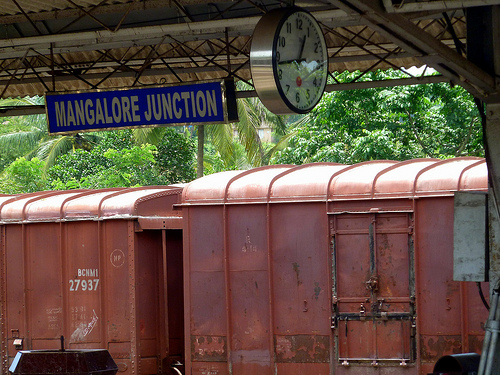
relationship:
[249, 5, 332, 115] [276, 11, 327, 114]
clock reads 12:43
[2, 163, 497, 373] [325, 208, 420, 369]
train car has door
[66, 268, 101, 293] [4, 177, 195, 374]
writing outside of train car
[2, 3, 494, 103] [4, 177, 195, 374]
awning over top of train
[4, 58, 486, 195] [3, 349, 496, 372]
greenery along train track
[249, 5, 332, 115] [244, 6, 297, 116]
clock made of metal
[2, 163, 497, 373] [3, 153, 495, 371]
train car part of set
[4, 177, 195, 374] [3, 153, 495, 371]
train car part of set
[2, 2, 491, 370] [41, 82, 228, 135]
train station at mangalore junction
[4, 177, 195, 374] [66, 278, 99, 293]
train has white numbers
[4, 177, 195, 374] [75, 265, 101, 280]
train has white letters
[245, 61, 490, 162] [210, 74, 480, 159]
tree has leaves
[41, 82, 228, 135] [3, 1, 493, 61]
sign hanging on ceiling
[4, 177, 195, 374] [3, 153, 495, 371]
train car on back end of train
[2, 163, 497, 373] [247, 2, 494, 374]
train car on right side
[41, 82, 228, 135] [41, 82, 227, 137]
sign says sign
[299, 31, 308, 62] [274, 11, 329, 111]
hand on clock face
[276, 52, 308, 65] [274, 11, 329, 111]
hand on clock face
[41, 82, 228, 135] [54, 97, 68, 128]
sign has letter m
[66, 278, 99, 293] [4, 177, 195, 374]
white numbers on side of train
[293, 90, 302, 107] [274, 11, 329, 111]
number 6 on clock face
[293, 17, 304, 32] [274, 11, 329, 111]
number 12 on clock face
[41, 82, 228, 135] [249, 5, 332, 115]
sign next to clock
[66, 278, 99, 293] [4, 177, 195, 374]
number 27937 on train car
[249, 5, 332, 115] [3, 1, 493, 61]
clock hanging from ceiling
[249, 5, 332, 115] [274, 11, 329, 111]
clock has white face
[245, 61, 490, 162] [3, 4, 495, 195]
tree in background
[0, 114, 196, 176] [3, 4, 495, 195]
tree in background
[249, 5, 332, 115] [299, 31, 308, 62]
clock has hand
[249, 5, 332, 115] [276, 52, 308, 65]
clock has hand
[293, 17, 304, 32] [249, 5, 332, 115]
number 12 on front of clock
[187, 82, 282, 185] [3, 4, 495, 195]
tree in background